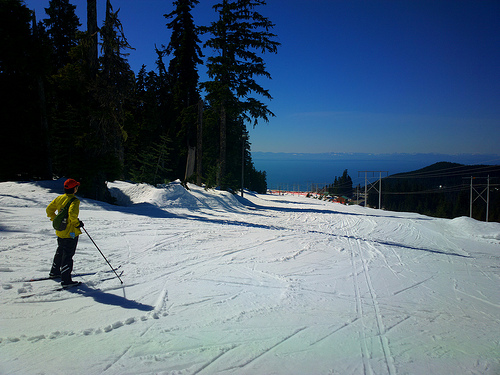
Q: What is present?
A: Snow.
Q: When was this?
A: Daytime.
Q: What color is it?
A: White.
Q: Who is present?
A: A person.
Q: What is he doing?
A: Skiing.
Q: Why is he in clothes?
A: To keep warm.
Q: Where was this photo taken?
A: At a ski slope.